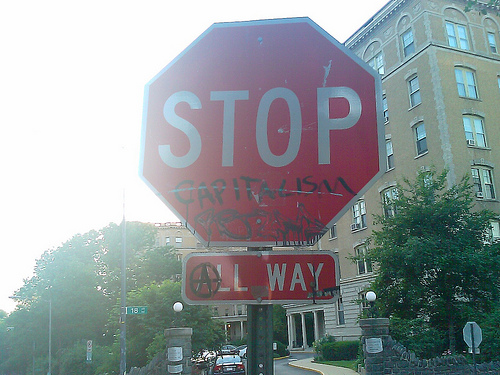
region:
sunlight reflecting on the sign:
[59, 125, 156, 185]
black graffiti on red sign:
[217, 170, 344, 197]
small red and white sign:
[151, 244, 363, 315]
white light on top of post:
[159, 298, 193, 325]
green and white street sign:
[109, 299, 159, 329]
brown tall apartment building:
[406, 70, 496, 250]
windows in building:
[437, 58, 488, 110]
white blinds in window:
[396, 120, 437, 147]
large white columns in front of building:
[278, 300, 338, 351]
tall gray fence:
[360, 317, 432, 361]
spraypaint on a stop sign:
[173, 174, 350, 200]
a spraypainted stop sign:
[182, 254, 339, 304]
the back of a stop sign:
[458, 319, 483, 345]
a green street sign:
[123, 305, 148, 315]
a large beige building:
[291, 2, 496, 346]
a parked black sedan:
[207, 353, 248, 373]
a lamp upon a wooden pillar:
[355, 292, 392, 372]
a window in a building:
[451, 65, 480, 99]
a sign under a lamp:
[362, 335, 383, 353]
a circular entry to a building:
[283, 303, 330, 350]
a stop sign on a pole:
[136, 12, 391, 322]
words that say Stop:
[148, 82, 363, 169]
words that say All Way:
[190, 263, 325, 299]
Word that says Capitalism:
[163, 170, 357, 212]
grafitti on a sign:
[167, 176, 364, 248]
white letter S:
[157, 86, 199, 171]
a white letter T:
[204, 83, 251, 172]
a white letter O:
[253, 85, 305, 172]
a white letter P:
[308, 80, 363, 172]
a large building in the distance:
[345, 12, 499, 245]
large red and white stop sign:
[141, 14, 386, 247]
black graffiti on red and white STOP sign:
[173, 177, 355, 245]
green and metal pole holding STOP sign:
[245, 303, 275, 373]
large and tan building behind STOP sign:
[285, 0, 498, 359]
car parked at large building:
[216, 353, 246, 370]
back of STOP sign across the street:
[461, 318, 486, 354]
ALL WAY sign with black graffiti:
[181, 249, 341, 306]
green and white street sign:
[125, 305, 149, 315]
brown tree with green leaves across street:
[346, 166, 498, 358]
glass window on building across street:
[453, 65, 480, 100]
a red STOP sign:
[89, 13, 401, 274]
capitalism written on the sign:
[172, 165, 371, 212]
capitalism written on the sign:
[129, 121, 385, 282]